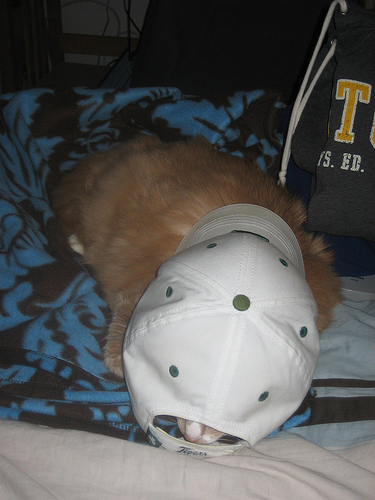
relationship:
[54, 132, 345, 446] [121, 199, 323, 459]
cat wearing hat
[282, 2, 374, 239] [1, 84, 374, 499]
shirt on bed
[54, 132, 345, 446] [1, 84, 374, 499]
cat on bed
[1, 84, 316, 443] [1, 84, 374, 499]
blanket on bed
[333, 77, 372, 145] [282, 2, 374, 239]
letter on shirt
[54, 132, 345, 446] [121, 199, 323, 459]
cat under hat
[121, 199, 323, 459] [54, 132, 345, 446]
hat on cat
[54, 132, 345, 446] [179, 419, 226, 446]
cat has nose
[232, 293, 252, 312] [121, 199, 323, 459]
button on hat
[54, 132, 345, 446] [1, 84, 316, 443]
cat on blanket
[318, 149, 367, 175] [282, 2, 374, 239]
letters on shirt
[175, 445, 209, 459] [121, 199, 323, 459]
word on hat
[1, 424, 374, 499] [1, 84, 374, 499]
sheet on bed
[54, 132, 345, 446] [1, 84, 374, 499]
cat laying on bed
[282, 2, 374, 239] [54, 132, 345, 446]
shirt beside cat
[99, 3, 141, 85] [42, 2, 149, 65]
cords against wall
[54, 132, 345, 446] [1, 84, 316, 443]
cat laying on blanket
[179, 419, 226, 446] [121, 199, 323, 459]
nose showing through hat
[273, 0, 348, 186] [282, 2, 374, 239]
string on shirt